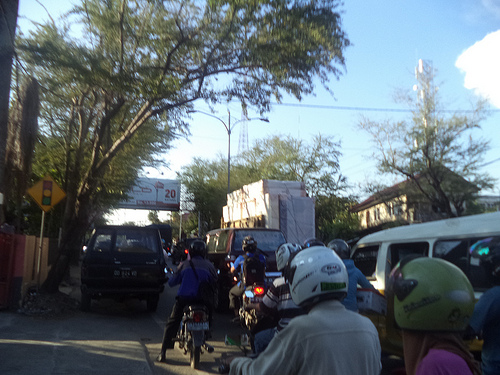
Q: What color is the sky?
A: Blue.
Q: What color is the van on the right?
A: White.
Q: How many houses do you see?
A: 1.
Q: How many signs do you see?
A: 2.